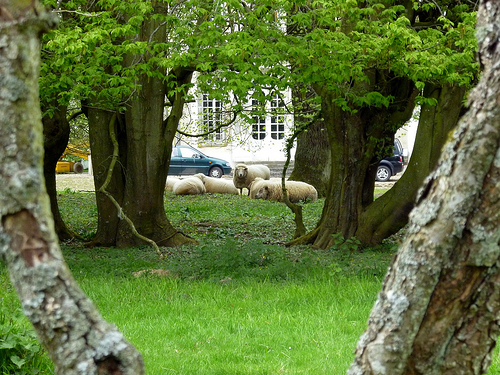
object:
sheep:
[196, 172, 237, 195]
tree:
[351, 32, 497, 375]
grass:
[2, 187, 499, 372]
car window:
[179, 147, 196, 157]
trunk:
[86, 61, 184, 247]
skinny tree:
[281, 124, 300, 169]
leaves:
[282, 92, 316, 127]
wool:
[289, 180, 309, 197]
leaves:
[295, 16, 472, 88]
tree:
[281, 0, 474, 248]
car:
[360, 129, 405, 187]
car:
[168, 143, 232, 181]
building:
[164, 5, 424, 165]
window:
[249, 89, 287, 141]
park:
[1, 2, 497, 371]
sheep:
[253, 176, 319, 204]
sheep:
[230, 161, 270, 197]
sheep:
[174, 173, 207, 196]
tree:
[5, 196, 141, 373]